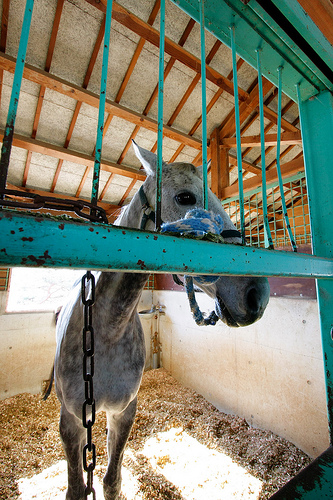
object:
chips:
[0, 396, 36, 450]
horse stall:
[0, 1, 333, 498]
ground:
[0, 365, 314, 500]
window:
[6, 266, 98, 313]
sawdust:
[0, 417, 305, 496]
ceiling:
[1, 1, 332, 207]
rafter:
[113, 34, 146, 106]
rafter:
[43, 0, 69, 79]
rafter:
[64, 94, 83, 153]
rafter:
[28, 79, 47, 139]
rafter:
[49, 156, 62, 193]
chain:
[47, 265, 122, 498]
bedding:
[0, 365, 315, 500]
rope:
[160, 206, 223, 328]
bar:
[89, 1, 115, 217]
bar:
[156, 0, 165, 232]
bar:
[200, 0, 207, 210]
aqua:
[0, 0, 332, 495]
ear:
[131, 138, 166, 177]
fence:
[0, 0, 318, 257]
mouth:
[210, 282, 247, 328]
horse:
[38, 137, 270, 500]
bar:
[229, 23, 245, 247]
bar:
[254, 48, 272, 249]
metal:
[154, 0, 167, 234]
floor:
[0, 368, 310, 500]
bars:
[275, 63, 300, 256]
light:
[140, 427, 263, 500]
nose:
[237, 279, 272, 323]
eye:
[174, 189, 197, 206]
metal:
[254, 49, 272, 248]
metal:
[89, 1, 112, 222]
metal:
[199, 2, 207, 213]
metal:
[0, 217, 333, 278]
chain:
[1, 188, 109, 226]